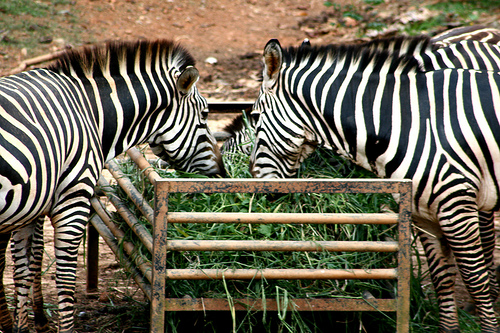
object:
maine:
[55, 39, 196, 75]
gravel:
[146, 7, 405, 40]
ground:
[164, 21, 315, 53]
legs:
[82, 216, 100, 291]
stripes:
[299, 61, 499, 166]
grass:
[136, 154, 390, 298]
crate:
[85, 101, 412, 333]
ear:
[177, 67, 200, 94]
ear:
[262, 38, 283, 78]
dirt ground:
[86, 3, 380, 37]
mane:
[278, 36, 431, 75]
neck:
[310, 40, 427, 179]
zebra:
[0, 37, 229, 327]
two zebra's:
[88, 37, 400, 164]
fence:
[93, 173, 414, 327]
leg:
[9, 219, 43, 331]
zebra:
[248, 35, 498, 331]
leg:
[48, 152, 97, 332]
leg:
[439, 200, 498, 330]